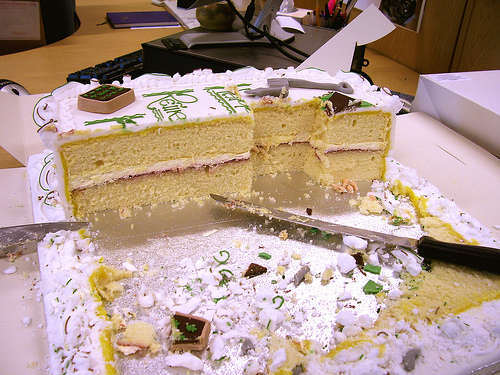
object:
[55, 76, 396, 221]
cake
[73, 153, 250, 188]
jelly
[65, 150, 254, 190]
middle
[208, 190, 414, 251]
blade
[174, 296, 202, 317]
crumbs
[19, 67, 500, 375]
platter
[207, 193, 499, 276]
knife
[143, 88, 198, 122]
designs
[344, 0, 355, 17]
pencils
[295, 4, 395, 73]
holder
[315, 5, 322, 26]
pens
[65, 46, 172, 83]
keyboard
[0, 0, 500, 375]
desk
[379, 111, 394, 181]
edge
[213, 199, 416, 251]
cutting edge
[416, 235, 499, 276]
handle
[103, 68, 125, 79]
buttons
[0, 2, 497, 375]
photo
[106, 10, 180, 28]
book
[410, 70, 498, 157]
box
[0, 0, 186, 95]
surface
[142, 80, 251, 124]
frosting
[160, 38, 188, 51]
remote